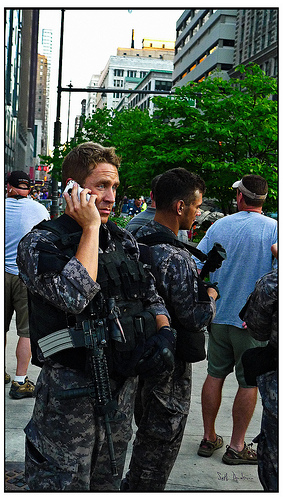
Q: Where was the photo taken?
A: It was taken at the street.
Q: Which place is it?
A: It is a street.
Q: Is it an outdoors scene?
A: Yes, it is outdoors.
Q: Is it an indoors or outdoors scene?
A: It is outdoors.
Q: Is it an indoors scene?
A: No, it is outdoors.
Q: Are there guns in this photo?
A: Yes, there is a gun.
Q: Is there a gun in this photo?
A: Yes, there is a gun.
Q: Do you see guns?
A: Yes, there is a gun.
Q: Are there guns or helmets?
A: Yes, there is a gun.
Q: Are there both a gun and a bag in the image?
A: No, there is a gun but no bags.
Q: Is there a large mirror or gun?
A: Yes, there is a large gun.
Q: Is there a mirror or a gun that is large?
A: Yes, the gun is large.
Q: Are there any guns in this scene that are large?
A: Yes, there is a large gun.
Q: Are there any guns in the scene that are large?
A: Yes, there is a gun that is large.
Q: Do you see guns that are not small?
A: Yes, there is a large gun.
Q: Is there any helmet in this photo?
A: No, there are no helmets.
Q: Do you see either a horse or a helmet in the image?
A: No, there are no helmets or horses.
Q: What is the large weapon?
A: The weapon is a gun.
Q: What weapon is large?
A: The weapon is a gun.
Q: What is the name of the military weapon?
A: The weapon is a gun.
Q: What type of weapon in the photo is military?
A: The weapon is a gun.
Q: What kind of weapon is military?
A: The weapon is a gun.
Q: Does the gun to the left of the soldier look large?
A: Yes, the gun is large.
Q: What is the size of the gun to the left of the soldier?
A: The gun is large.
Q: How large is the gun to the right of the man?
A: The gun is large.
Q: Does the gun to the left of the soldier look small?
A: No, the gun is large.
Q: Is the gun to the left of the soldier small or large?
A: The gun is large.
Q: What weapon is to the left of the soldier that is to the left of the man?
A: The weapon is a gun.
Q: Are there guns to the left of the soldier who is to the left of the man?
A: Yes, there is a gun to the left of the soldier.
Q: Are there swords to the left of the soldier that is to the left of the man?
A: No, there is a gun to the left of the soldier.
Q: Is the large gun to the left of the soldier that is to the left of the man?
A: Yes, the gun is to the left of the soldier.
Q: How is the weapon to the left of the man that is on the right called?
A: The weapon is a gun.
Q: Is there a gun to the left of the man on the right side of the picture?
A: Yes, there is a gun to the left of the man.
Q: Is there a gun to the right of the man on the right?
A: No, the gun is to the left of the man.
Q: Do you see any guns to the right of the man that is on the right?
A: No, the gun is to the left of the man.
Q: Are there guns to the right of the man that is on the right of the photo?
A: No, the gun is to the left of the man.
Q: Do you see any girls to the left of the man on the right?
A: No, there is a gun to the left of the man.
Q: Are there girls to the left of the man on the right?
A: No, there is a gun to the left of the man.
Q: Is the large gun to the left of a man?
A: Yes, the gun is to the left of a man.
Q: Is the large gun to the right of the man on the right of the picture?
A: No, the gun is to the left of the man.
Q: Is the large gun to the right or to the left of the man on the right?
A: The gun is to the left of the man.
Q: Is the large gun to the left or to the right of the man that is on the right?
A: The gun is to the left of the man.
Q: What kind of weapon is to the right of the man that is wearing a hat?
A: The weapon is a gun.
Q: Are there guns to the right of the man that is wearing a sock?
A: Yes, there is a gun to the right of the man.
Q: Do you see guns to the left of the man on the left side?
A: No, the gun is to the right of the man.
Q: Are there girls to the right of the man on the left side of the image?
A: No, there is a gun to the right of the man.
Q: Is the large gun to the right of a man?
A: Yes, the gun is to the right of a man.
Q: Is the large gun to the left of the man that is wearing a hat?
A: No, the gun is to the right of the man.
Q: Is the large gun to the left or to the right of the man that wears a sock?
A: The gun is to the right of the man.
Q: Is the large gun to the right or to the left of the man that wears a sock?
A: The gun is to the right of the man.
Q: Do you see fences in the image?
A: No, there are no fences.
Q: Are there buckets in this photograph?
A: No, there are no buckets.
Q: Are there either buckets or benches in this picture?
A: No, there are no buckets or benches.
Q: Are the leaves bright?
A: Yes, the leaves are bright.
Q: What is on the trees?
A: The leaves are on the trees.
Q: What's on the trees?
A: The leaves are on the trees.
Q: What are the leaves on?
A: The leaves are on the trees.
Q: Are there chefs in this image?
A: No, there are no chefs.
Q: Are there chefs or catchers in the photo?
A: No, there are no chefs or catchers.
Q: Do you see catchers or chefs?
A: No, there are no chefs or catchers.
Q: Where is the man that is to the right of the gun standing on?
A: The man is standing on the street.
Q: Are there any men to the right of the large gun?
A: Yes, there is a man to the right of the gun.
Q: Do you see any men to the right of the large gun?
A: Yes, there is a man to the right of the gun.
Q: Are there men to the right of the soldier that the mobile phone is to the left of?
A: Yes, there is a man to the right of the soldier.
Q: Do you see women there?
A: No, there are no women.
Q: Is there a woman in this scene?
A: No, there are no women.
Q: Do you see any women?
A: No, there are no women.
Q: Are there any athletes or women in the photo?
A: No, there are no women or athletes.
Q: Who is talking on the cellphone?
A: The man is talking on the cellphone.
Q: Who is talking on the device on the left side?
A: The man is talking on the cellphone.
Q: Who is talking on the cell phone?
A: The man is talking on the cellphone.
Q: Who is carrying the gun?
A: The man is carrying the gun.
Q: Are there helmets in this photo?
A: No, there are no helmets.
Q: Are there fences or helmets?
A: No, there are no helmets or fences.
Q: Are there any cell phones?
A: Yes, there is a cell phone.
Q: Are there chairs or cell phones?
A: Yes, there is a cell phone.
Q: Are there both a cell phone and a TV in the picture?
A: No, there is a cell phone but no televisions.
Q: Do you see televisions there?
A: No, there are no televisions.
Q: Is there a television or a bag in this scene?
A: No, there are no televisions or bags.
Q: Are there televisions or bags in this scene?
A: No, there are no televisions or bags.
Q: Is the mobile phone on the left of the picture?
A: Yes, the mobile phone is on the left of the image.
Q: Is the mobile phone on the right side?
A: No, the mobile phone is on the left of the image.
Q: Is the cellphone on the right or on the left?
A: The cellphone is on the left of the image.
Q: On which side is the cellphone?
A: The cellphone is on the left of the image.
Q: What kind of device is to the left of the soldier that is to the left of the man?
A: The device is a cell phone.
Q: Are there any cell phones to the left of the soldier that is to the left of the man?
A: Yes, there is a cell phone to the left of the soldier.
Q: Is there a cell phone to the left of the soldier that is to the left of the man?
A: Yes, there is a cell phone to the left of the soldier.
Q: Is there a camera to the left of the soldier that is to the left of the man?
A: No, there is a cell phone to the left of the soldier.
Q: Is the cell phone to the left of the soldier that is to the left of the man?
A: Yes, the cell phone is to the left of the soldier.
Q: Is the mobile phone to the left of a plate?
A: No, the mobile phone is to the left of the soldier.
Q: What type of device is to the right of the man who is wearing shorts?
A: The device is a cell phone.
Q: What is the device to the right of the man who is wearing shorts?
A: The device is a cell phone.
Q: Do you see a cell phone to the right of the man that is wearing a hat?
A: Yes, there is a cell phone to the right of the man.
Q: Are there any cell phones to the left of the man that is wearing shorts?
A: No, the cell phone is to the right of the man.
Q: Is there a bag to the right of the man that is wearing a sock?
A: No, there is a cell phone to the right of the man.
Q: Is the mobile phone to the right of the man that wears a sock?
A: Yes, the mobile phone is to the right of the man.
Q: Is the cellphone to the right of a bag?
A: No, the cellphone is to the right of the man.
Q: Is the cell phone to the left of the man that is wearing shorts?
A: No, the cell phone is to the right of the man.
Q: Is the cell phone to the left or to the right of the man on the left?
A: The cell phone is to the right of the man.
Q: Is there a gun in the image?
A: Yes, there is a gun.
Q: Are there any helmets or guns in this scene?
A: Yes, there is a gun.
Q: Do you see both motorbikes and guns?
A: No, there is a gun but no motorcycles.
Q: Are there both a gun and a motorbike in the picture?
A: No, there is a gun but no motorcycles.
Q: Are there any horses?
A: No, there are no horses.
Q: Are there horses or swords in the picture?
A: No, there are no horses or swords.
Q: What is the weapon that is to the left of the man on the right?
A: The weapon is a gun.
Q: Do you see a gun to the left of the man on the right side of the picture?
A: Yes, there is a gun to the left of the man.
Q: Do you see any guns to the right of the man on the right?
A: No, the gun is to the left of the man.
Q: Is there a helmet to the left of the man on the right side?
A: No, there is a gun to the left of the man.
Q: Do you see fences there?
A: No, there are no fences.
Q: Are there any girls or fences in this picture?
A: No, there are no fences or girls.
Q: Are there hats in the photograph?
A: Yes, there is a hat.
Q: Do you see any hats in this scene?
A: Yes, there is a hat.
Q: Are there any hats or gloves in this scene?
A: Yes, there is a hat.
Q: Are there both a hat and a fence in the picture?
A: No, there is a hat but no fences.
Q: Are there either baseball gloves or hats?
A: Yes, there is a baseball hat.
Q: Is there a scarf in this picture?
A: No, there are no scarves.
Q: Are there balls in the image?
A: No, there are no balls.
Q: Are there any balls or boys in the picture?
A: No, there are no balls or boys.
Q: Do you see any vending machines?
A: No, there are no vending machines.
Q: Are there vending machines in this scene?
A: No, there are no vending machines.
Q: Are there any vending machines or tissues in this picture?
A: No, there are no vending machines or tissues.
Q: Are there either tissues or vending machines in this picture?
A: No, there are no vending machines or tissues.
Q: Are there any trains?
A: No, there are no trains.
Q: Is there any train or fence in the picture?
A: No, there are no trains or fences.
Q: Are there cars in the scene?
A: No, there are no cars.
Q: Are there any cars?
A: No, there are no cars.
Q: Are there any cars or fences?
A: No, there are no cars or fences.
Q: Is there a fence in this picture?
A: No, there are no fences.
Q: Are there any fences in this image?
A: No, there are no fences.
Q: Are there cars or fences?
A: No, there are no fences or cars.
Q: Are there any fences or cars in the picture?
A: No, there are no fences or cars.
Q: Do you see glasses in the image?
A: No, there are no glasses.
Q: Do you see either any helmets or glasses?
A: No, there are no glasses or helmets.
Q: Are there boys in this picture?
A: No, there are no boys.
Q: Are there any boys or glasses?
A: No, there are no boys or glasses.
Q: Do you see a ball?
A: No, there are no balls.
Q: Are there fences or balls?
A: No, there are no balls or fences.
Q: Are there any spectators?
A: No, there are no spectators.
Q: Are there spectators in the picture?
A: No, there are no spectators.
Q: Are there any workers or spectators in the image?
A: No, there are no spectators or workers.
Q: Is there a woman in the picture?
A: No, there are no women.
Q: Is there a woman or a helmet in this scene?
A: No, there are no women or helmets.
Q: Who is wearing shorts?
A: The man is wearing shorts.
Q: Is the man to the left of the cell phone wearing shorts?
A: Yes, the man is wearing shorts.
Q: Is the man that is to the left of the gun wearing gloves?
A: No, the man is wearing shorts.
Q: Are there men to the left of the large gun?
A: Yes, there is a man to the left of the gun.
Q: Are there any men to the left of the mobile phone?
A: Yes, there is a man to the left of the mobile phone.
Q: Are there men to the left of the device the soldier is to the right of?
A: Yes, there is a man to the left of the mobile phone.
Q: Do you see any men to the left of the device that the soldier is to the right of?
A: Yes, there is a man to the left of the mobile phone.